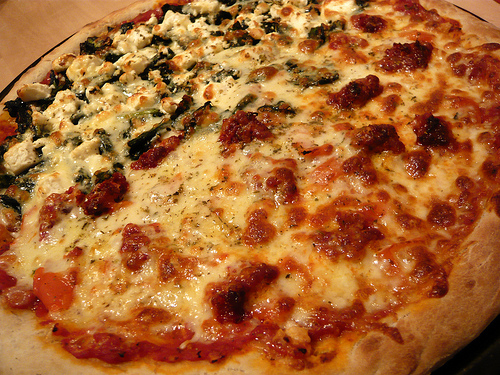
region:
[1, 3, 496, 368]
this is a pizza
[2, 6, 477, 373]
there are different halves of the pizza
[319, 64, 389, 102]
a piece of sausage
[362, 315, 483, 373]
part of the pizza crust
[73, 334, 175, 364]
this is red tomato sauce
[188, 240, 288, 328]
some of the cheese is burnt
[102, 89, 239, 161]
a piece of spinach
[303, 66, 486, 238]
this section of the pizza is topped with sausage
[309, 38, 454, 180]
sausage topping on pizza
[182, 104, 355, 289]
A pizza in the photo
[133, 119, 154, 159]
Brocolli on the pizza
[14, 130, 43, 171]
Mushroom on the pizza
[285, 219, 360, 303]
Sauce on the pizza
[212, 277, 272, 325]
Red sauce on the pizza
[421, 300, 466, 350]
Baked wheat dough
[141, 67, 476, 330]
A pizza on the table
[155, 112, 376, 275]
A pizza on the box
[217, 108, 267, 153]
Meat on the pizza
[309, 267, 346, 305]
Egg yolk on the pizza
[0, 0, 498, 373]
the cooked pizza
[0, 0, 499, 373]
the crust on the pizza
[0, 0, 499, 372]
the toppings on the pizza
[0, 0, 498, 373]
the cheese on the pizza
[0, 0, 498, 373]
the tomato sauce on the pizza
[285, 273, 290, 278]
the spice on the pizza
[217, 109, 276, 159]
the brown piece of meat on the pizza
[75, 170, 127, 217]
the spice on the pizza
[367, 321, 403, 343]
the piece of brown cheese on the crust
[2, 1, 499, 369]
A pizza with different toppings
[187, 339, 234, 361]
The sauce is red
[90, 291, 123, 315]
The cheese is yellow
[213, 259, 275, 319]
A piece of burned cheest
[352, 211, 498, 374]
The crust is brown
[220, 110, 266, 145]
sausage on the pizza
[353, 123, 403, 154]
the sausage is brown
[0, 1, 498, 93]
Table under the pizza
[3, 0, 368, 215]
chicken and spinach on pizza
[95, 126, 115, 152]
the spinach is green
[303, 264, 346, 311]
cheese on a pizza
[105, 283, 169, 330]
cheese on a pizza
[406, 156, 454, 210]
cheese on a pizza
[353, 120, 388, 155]
cheese on a pizza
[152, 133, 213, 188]
cheese on a pizza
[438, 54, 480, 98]
cheese on a pizza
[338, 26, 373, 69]
cheese on a pizza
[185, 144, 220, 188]
cheese on a pizza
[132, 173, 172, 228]
cheese on a pizza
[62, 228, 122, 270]
cheese on a pizza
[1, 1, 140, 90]
Largest area of brown table.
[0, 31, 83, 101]
Black edge of a pan near the largest wooden part of a table.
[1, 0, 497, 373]
A large pizza with spinach on half.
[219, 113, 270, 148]
Largest piece of middle meat.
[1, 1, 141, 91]
Large brown part of a table.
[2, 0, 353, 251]
Half of a cheesy pizza with chicken and spinach.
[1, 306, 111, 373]
Large area of crust under an orange vegetable.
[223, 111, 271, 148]
Middle most piece of meat.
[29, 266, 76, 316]
Largest orange chunk of vegetable.